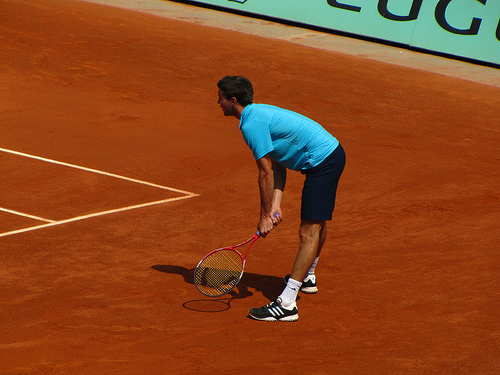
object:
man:
[216, 76, 346, 323]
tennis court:
[0, 0, 500, 375]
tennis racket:
[194, 212, 280, 296]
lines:
[59, 211, 107, 224]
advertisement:
[188, 0, 499, 70]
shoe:
[249, 299, 298, 320]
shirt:
[238, 103, 338, 172]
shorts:
[298, 143, 347, 222]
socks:
[277, 278, 302, 307]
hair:
[217, 75, 253, 107]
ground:
[96, 67, 150, 143]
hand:
[258, 217, 275, 238]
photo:
[7, 0, 484, 375]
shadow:
[150, 265, 300, 306]